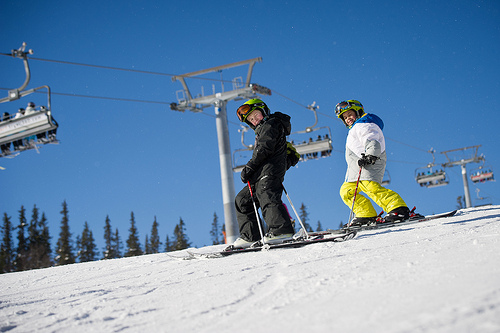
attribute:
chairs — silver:
[0, 52, 67, 155]